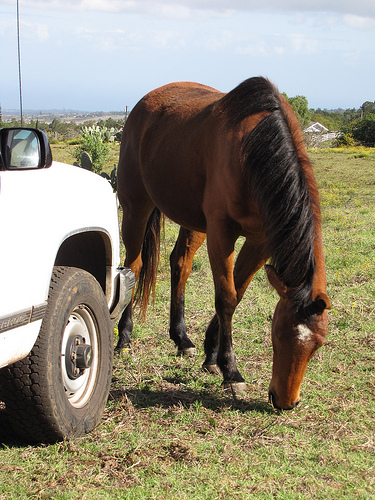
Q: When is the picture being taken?
A: Daytime.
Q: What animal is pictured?
A: Horse.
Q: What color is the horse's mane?
A: Black.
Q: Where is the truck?
A: On the left.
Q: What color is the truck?
A: White.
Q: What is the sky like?
A: Partly cloudy.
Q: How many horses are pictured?
A: One.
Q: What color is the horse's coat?
A: Brown.